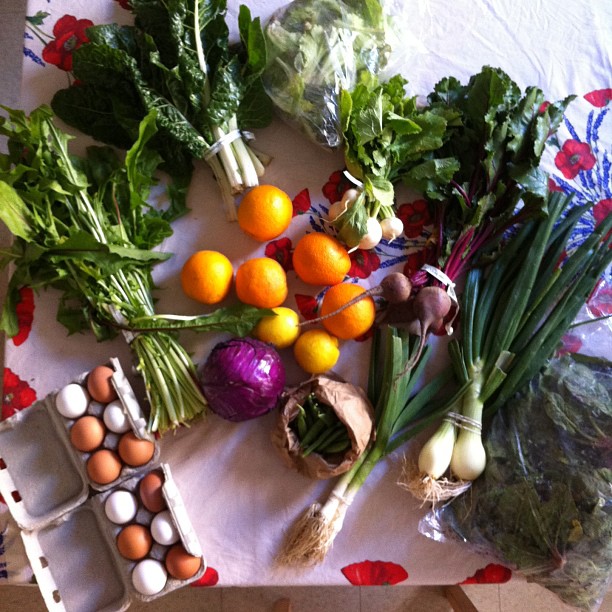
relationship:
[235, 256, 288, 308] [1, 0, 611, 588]
fruit on table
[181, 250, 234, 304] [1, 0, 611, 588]
fruit on table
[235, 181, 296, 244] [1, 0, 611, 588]
orange on table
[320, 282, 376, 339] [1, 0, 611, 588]
fruit on table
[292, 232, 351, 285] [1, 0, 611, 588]
fruit on table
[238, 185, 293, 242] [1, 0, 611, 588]
fruit on table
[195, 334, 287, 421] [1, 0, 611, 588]
onion on table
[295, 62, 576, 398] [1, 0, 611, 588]
beets on table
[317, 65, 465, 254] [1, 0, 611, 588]
cabbage on table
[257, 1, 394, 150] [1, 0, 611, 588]
vegetable on table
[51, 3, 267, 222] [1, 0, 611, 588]
vegetable on table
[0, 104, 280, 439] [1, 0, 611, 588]
leafy vegetable on table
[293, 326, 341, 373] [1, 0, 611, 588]
fruit on table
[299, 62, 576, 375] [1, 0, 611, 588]
beets on table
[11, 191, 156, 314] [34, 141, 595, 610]
vegetable on table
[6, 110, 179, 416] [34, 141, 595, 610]
leafy vegetable on table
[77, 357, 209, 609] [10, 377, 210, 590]
eggs in carton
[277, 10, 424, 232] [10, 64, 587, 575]
cabbage sitting on table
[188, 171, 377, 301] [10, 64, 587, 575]
oranges on table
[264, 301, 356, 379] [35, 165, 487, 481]
lemons on table